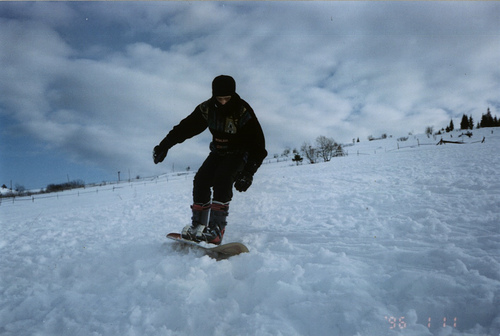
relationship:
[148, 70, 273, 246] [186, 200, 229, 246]
person wearing boots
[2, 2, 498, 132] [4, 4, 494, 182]
clouds in sky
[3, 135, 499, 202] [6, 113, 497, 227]
fence in background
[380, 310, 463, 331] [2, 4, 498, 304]
date on picture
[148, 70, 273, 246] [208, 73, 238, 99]
person wearing hat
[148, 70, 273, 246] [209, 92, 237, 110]
person wearing ski mask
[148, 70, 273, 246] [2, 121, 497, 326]
person on hill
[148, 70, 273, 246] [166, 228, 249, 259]
person on snowboard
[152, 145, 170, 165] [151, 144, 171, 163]
glove on hand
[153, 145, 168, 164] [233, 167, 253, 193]
hand on hand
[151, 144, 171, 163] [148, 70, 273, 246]
hand on person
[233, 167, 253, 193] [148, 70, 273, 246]
hand on person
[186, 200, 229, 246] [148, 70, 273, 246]
boots on person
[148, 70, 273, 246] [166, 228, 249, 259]
person using surfboard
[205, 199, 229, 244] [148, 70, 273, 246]
boot on person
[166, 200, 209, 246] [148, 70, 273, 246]
boots on person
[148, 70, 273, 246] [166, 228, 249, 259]
person using snowboard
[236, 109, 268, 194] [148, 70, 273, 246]
arm of person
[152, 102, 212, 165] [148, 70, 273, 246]
arm of person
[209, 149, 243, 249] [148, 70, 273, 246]
leg of person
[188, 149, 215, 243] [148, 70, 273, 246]
leg of person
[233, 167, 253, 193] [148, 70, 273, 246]
hand of person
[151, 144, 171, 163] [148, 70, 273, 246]
hand of person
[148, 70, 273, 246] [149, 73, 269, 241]
person in black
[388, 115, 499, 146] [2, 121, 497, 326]
top of hill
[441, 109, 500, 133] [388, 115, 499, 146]
evergreens on top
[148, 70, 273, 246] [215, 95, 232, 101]
person has eyes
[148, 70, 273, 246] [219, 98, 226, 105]
person has nose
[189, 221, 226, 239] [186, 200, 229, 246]
straps across boots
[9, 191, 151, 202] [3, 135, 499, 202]
posts of fence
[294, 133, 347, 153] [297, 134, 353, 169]
branches on bushes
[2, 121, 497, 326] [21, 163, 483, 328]
snow over place